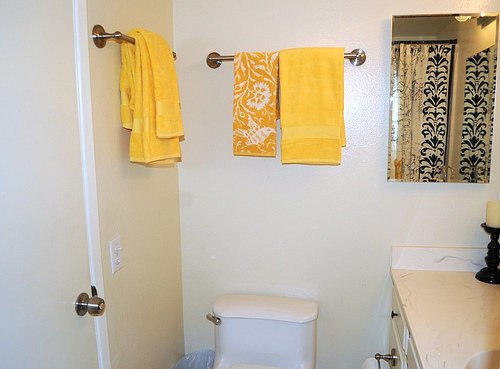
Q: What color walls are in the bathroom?
A: White.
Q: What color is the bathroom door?
A: White.